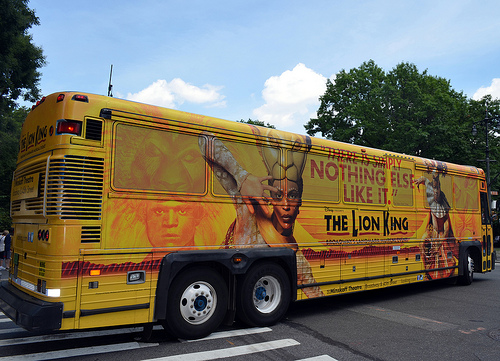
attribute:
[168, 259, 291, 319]
wheels — black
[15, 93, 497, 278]
bus — yellow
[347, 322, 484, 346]
road — gray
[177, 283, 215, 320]
rim — white